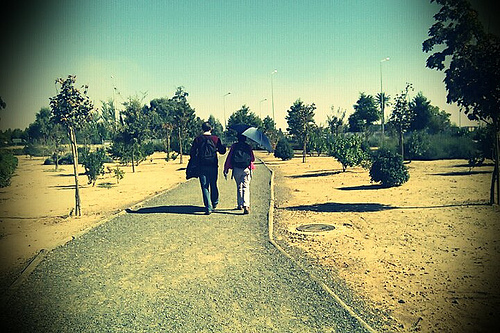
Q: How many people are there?
A: Two.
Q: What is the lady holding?
A: An umbrella.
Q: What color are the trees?
A: Green.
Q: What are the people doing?
A: Walking.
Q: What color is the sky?
A: Blue.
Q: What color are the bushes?
A: Green.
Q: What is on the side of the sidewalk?
A: Sand.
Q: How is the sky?
A: Clear and blue.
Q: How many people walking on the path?
A: Two.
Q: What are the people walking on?
A: Gravel walking path.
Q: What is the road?
A: Tarmacked.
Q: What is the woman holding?
A: An umbrella.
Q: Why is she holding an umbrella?
A: It's very sunny.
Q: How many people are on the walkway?
A: Two.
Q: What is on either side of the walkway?
A: Dirt.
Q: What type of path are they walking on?
A: Gravel.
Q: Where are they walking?
A: In a park.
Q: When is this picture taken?
A: Daytime.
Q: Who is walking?
A: A man and a woman.